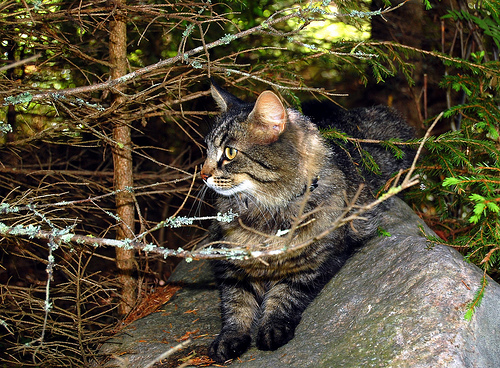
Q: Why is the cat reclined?
A: Resting.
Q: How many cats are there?
A: One.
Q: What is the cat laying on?
A: Rock.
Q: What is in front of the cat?
A: Branch.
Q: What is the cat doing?
A: Watching.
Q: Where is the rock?
A: Woods.